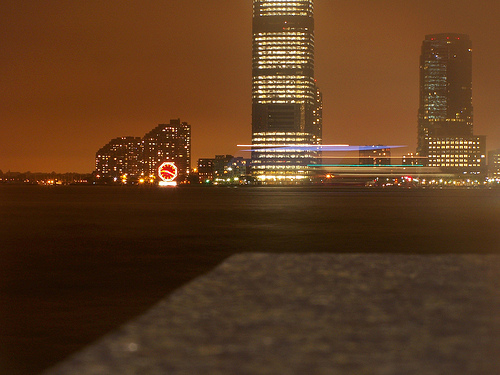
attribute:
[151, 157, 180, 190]
clock — circular, neon, lit up, red, light up, large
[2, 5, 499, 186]
city — lit up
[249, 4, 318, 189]
building — lit, tall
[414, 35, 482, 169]
building — tall, lit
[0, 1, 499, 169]
sky — brown, purple, burnt orange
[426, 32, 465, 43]
lights — red, bright, on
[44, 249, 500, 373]
slab — painted, concrete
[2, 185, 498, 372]
water — dark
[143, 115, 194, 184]
building — small